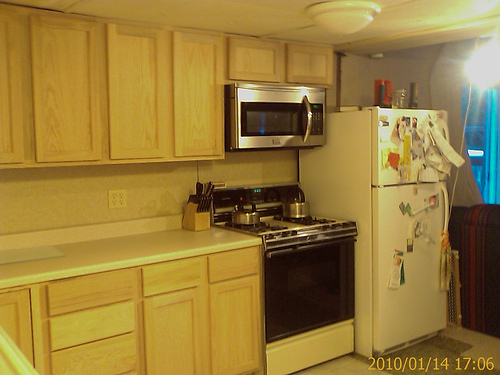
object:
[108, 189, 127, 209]
socket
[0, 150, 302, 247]
wall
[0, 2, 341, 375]
cabinets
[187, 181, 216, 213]
knives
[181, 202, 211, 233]
knife block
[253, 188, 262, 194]
time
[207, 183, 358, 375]
oven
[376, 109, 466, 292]
objects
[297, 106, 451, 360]
refrigerator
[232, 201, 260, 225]
tea kettle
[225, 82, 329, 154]
microwave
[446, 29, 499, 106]
light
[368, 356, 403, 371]
2010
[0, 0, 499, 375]
photo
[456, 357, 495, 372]
17:06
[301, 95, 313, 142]
handle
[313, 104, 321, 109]
time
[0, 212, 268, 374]
counter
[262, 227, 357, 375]
door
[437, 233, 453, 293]
hand towel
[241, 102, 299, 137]
window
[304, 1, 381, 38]
light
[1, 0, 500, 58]
ceiling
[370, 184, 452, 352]
door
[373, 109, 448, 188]
door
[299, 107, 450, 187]
freezer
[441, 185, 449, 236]
handle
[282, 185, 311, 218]
tea kettle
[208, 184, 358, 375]
stove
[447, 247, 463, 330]
gate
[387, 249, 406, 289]
paper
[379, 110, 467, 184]
papers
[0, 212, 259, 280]
cutting board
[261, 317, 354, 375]
storage drawer